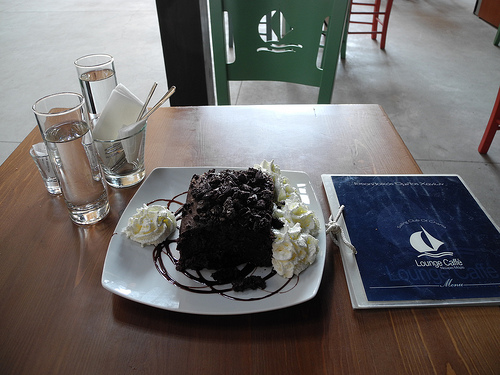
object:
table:
[2, 102, 498, 375]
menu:
[322, 171, 499, 308]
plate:
[100, 167, 328, 313]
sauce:
[122, 157, 320, 301]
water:
[42, 120, 108, 208]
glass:
[29, 90, 111, 223]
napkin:
[90, 83, 150, 168]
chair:
[206, 0, 348, 105]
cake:
[175, 167, 283, 271]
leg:
[478, 80, 499, 155]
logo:
[404, 226, 458, 257]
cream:
[125, 203, 176, 246]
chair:
[344, 0, 392, 53]